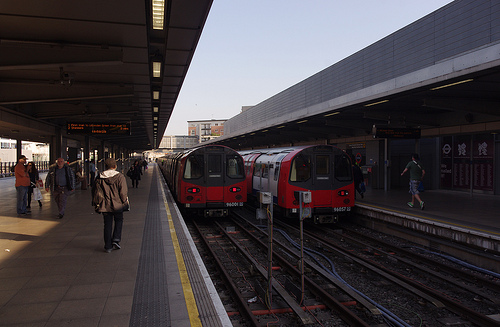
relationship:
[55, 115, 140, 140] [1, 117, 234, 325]
sign on platform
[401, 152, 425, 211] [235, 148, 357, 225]
man walking next to train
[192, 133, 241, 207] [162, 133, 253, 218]
door on train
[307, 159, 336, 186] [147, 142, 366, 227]
window on train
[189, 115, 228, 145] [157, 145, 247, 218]
building behind passenger train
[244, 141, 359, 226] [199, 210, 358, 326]
train on track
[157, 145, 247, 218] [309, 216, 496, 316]
passenger train on track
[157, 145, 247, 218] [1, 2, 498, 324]
passenger train stopped at station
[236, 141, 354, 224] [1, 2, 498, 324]
train stopped at station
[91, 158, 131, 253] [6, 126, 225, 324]
man at train station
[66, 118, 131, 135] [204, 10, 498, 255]
sign at station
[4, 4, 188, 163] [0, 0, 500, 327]
awning at a station